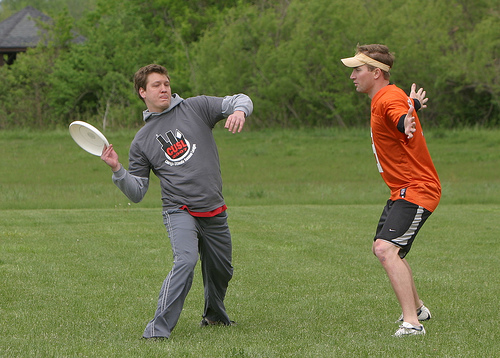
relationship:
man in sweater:
[94, 57, 267, 344] [110, 91, 257, 214]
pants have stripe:
[142, 206, 237, 343] [161, 210, 179, 326]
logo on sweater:
[150, 126, 205, 172] [110, 91, 257, 214]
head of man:
[131, 60, 176, 114] [94, 57, 267, 344]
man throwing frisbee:
[94, 57, 267, 344] [66, 112, 110, 161]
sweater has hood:
[110, 91, 257, 206] [134, 88, 187, 122]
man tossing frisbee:
[94, 57, 267, 344] [66, 112, 110, 161]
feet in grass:
[135, 314, 239, 345] [0, 124, 500, 356]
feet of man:
[135, 314, 239, 345] [94, 57, 267, 344]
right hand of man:
[97, 142, 123, 171] [94, 57, 267, 344]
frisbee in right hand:
[66, 112, 110, 161] [97, 142, 123, 171]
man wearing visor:
[336, 40, 444, 343] [337, 48, 394, 77]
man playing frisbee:
[100, 62, 256, 346] [66, 112, 110, 161]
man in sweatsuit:
[94, 57, 267, 344] [110, 88, 259, 339]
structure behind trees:
[2, 1, 89, 71] [2, 0, 497, 133]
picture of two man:
[0, 0, 499, 356] [100, 62, 256, 346]